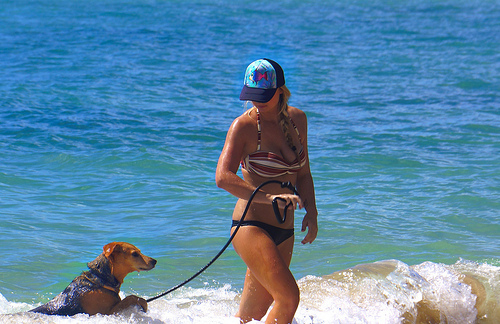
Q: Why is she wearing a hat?
A: To protect from sun.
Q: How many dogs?
A: One.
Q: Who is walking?
A: Woman.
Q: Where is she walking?
A: Beach.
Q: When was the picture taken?
A: Daytime.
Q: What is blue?
A: Water.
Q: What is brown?
A: Dog.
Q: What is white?
A: Waves.